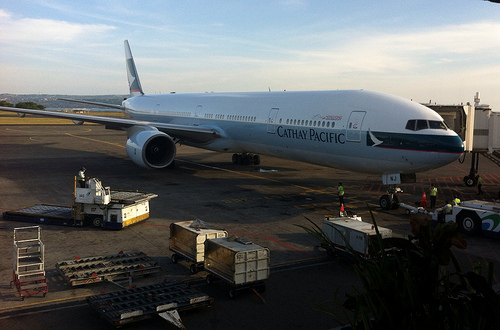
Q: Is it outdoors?
A: Yes, it is outdoors.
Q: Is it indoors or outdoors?
A: It is outdoors.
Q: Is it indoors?
A: No, it is outdoors.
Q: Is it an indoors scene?
A: No, it is outdoors.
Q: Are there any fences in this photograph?
A: No, there are no fences.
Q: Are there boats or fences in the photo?
A: No, there are no fences or boats.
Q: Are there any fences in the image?
A: No, there are no fences.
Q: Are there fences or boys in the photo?
A: No, there are no fences or boys.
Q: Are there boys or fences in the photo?
A: No, there are no fences or boys.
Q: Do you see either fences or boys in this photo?
A: No, there are no fences or boys.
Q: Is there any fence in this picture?
A: No, there are no fences.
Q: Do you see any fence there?
A: No, there are no fences.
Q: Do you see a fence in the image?
A: No, there are no fences.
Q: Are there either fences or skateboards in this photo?
A: No, there are no fences or skateboards.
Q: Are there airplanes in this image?
A: Yes, there is an airplane.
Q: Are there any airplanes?
A: Yes, there is an airplane.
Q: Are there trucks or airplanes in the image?
A: Yes, there is an airplane.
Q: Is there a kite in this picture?
A: No, there are no kites.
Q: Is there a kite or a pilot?
A: No, there are no kites or pilots.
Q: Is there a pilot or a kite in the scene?
A: No, there are no kites or pilots.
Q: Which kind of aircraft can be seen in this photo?
A: The aircraft is an airplane.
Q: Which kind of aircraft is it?
A: The aircraft is an airplane.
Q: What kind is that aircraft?
A: This is an airplane.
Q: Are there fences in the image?
A: No, there are no fences.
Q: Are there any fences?
A: No, there are no fences.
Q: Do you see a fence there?
A: No, there are no fences.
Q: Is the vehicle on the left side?
A: Yes, the vehicle is on the left of the image.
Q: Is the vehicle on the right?
A: No, the vehicle is on the left of the image.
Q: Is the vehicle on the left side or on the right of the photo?
A: The vehicle is on the left of the image.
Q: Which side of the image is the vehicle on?
A: The vehicle is on the left of the image.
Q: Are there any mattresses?
A: No, there are no mattresses.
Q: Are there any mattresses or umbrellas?
A: No, there are no mattresses or umbrellas.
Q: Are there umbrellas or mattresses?
A: No, there are no mattresses or umbrellas.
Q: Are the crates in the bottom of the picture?
A: Yes, the crates are in the bottom of the image.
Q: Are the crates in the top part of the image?
A: No, the crates are in the bottom of the image.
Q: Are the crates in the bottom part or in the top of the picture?
A: The crates are in the bottom of the image.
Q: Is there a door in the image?
A: Yes, there is a door.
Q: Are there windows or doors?
A: Yes, there is a door.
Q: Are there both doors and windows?
A: Yes, there are both a door and a window.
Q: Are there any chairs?
A: No, there are no chairs.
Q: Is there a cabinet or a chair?
A: No, there are no chairs or cabinets.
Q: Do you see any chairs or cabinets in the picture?
A: No, there are no chairs or cabinets.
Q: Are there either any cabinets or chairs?
A: No, there are no chairs or cabinets.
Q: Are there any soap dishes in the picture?
A: No, there are no soap dishes.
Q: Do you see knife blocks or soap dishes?
A: No, there are no soap dishes or knife blocks.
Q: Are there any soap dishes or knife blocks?
A: No, there are no soap dishes or knife blocks.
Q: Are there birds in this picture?
A: No, there are no birds.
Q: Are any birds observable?
A: No, there are no birds.